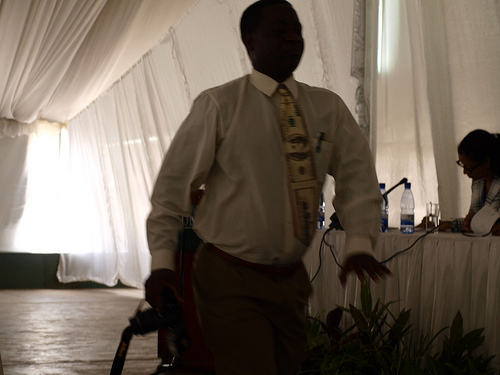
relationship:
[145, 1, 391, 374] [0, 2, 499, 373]
man at wedding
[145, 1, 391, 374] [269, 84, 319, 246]
man wearing a tie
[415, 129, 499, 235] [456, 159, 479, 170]
woman with glasses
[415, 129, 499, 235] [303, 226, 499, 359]
woman at a table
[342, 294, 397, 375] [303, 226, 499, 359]
plant by a table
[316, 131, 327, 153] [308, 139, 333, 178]
stuff in pocket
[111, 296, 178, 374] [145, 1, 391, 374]
cane next to man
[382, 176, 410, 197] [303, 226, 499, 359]
microphone on table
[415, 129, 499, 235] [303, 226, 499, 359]
woman sitting at an event table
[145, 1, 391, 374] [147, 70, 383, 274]
man wearing a shirt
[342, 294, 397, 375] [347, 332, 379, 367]
plant in a planter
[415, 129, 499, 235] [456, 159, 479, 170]
woman wearing glasses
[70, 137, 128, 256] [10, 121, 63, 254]
sunlight coming through window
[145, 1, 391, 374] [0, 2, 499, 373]
man walking in wedding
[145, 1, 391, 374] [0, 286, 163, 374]
man dancing on floor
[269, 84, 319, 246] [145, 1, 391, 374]
tie on man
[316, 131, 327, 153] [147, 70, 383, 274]
stuff in shirt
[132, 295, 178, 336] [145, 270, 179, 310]
camera in hand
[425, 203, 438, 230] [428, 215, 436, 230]
glass of water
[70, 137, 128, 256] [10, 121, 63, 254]
sunlight shining through window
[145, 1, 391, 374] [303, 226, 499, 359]
man standing in front of table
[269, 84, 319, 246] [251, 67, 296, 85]
tie around neck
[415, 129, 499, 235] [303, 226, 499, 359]
woman at table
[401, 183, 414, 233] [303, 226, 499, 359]
bottle on table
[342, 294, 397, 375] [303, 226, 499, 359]
plant in front of table